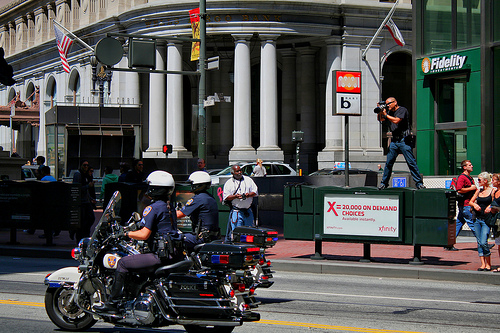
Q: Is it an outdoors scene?
A: Yes, it is outdoors.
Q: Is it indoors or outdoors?
A: It is outdoors.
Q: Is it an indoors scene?
A: No, it is outdoors.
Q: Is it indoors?
A: No, it is outdoors.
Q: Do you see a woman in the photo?
A: Yes, there is a woman.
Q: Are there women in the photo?
A: Yes, there is a woman.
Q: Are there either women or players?
A: Yes, there is a woman.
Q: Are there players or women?
A: Yes, there is a woman.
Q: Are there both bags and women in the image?
A: No, there is a woman but no bags.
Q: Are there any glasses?
A: No, there are no glasses.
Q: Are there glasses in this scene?
A: No, there are no glasses.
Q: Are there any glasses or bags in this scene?
A: No, there are no glasses or bags.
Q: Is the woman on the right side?
A: Yes, the woman is on the right of the image.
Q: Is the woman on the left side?
A: No, the woman is on the right of the image.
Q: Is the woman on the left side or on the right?
A: The woman is on the right of the image.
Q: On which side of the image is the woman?
A: The woman is on the right of the image.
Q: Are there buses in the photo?
A: No, there are no buses.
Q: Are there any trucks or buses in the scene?
A: No, there are no buses or trucks.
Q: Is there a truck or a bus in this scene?
A: No, there are no buses or trucks.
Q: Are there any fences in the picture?
A: No, there are no fences.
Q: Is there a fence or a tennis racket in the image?
A: No, there are no fences or rackets.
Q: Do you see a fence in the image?
A: No, there are no fences.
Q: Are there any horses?
A: No, there are no horses.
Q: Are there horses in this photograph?
A: No, there are no horses.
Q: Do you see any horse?
A: No, there are no horses.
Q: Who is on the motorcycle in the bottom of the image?
A: The officer is on the motorcycle.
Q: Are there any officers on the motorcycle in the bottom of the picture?
A: Yes, there is an officer on the motorbike.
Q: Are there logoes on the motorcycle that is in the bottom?
A: No, there is an officer on the motorbike.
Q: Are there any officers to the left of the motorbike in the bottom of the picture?
A: Yes, there is an officer to the left of the motorcycle.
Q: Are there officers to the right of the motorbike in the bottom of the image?
A: No, the officer is to the left of the motorcycle.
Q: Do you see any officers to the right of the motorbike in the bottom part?
A: No, the officer is to the left of the motorcycle.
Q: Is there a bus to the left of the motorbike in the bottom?
A: No, there is an officer to the left of the motorbike.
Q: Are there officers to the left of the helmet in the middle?
A: Yes, there is an officer to the left of the helmet.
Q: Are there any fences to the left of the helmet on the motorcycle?
A: No, there is an officer to the left of the helmet.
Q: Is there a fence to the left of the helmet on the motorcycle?
A: No, there is an officer to the left of the helmet.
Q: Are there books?
A: No, there are no books.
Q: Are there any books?
A: No, there are no books.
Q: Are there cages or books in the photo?
A: No, there are no books or cages.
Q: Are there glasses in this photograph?
A: No, there are no glasses.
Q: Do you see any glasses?
A: No, there are no glasses.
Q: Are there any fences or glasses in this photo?
A: No, there are no glasses or fences.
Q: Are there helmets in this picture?
A: Yes, there is a helmet.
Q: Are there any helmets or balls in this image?
A: Yes, there is a helmet.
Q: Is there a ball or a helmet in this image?
A: Yes, there is a helmet.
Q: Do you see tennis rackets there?
A: No, there are no tennis rackets.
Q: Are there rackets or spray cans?
A: No, there are no rackets or spray cans.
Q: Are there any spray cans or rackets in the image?
A: No, there are no rackets or spray cans.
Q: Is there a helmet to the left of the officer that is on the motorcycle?
A: Yes, there is a helmet to the left of the officer.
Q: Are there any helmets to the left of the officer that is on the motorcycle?
A: Yes, there is a helmet to the left of the officer.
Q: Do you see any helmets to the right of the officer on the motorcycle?
A: No, the helmet is to the left of the officer.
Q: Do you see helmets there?
A: Yes, there is a helmet.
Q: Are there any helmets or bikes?
A: Yes, there is a helmet.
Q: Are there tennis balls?
A: No, there are no tennis balls.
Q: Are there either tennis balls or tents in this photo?
A: No, there are no tennis balls or tents.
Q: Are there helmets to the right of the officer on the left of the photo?
A: Yes, there is a helmet to the right of the officer.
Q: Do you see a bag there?
A: No, there are no bags.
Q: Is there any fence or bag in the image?
A: No, there are no bags or fences.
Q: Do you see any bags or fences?
A: No, there are no bags or fences.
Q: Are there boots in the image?
A: Yes, there are boots.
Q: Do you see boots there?
A: Yes, there are boots.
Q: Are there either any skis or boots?
A: Yes, there are boots.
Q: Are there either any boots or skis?
A: Yes, there are boots.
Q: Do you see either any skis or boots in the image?
A: Yes, there are boots.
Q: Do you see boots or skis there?
A: Yes, there are boots.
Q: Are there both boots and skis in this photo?
A: No, there are boots but no skis.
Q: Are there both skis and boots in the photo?
A: No, there are boots but no skis.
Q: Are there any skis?
A: No, there are no skis.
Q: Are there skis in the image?
A: No, there are no skis.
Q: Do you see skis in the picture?
A: No, there are no skis.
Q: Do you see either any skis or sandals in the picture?
A: No, there are no skis or sandals.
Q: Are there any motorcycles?
A: Yes, there is a motorcycle.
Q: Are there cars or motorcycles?
A: Yes, there is a motorcycle.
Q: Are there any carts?
A: No, there are no carts.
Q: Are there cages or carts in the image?
A: No, there are no carts or cages.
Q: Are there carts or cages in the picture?
A: No, there are no carts or cages.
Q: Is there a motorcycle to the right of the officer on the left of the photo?
A: Yes, there is a motorcycle to the right of the officer.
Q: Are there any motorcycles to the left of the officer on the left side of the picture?
A: No, the motorcycle is to the right of the officer.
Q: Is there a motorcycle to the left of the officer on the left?
A: No, the motorcycle is to the right of the officer.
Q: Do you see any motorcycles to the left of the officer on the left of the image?
A: No, the motorcycle is to the right of the officer.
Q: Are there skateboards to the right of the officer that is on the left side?
A: No, there is a motorcycle to the right of the officer.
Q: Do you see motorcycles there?
A: Yes, there is a motorcycle.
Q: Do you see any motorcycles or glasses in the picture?
A: Yes, there is a motorcycle.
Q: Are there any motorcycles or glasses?
A: Yes, there is a motorcycle.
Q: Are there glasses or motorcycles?
A: Yes, there is a motorcycle.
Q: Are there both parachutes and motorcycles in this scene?
A: No, there is a motorcycle but no parachutes.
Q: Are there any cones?
A: No, there are no cones.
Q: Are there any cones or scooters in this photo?
A: No, there are no cones or scooters.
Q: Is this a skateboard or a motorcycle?
A: This is a motorcycle.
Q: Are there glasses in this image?
A: No, there are no glasses.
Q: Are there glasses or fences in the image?
A: No, there are no glasses or fences.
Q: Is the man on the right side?
A: Yes, the man is on the right of the image.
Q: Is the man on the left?
A: No, the man is on the right of the image.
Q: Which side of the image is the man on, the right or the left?
A: The man is on the right of the image.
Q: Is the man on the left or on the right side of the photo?
A: The man is on the right of the image.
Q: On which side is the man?
A: The man is on the right of the image.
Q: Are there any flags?
A: Yes, there is a flag.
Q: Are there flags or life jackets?
A: Yes, there is a flag.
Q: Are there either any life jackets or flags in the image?
A: Yes, there is a flag.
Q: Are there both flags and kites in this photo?
A: No, there is a flag but no kites.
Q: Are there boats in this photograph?
A: No, there are no boats.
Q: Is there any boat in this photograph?
A: No, there are no boats.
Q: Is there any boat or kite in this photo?
A: No, there are no boats or kites.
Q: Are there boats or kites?
A: No, there are no boats or kites.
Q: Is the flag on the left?
A: Yes, the flag is on the left of the image.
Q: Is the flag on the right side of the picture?
A: No, the flag is on the left of the image.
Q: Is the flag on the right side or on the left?
A: The flag is on the left of the image.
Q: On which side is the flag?
A: The flag is on the left of the image.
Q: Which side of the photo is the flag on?
A: The flag is on the left of the image.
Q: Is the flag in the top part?
A: Yes, the flag is in the top of the image.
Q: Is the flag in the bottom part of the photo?
A: No, the flag is in the top of the image.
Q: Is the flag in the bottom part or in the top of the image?
A: The flag is in the top of the image.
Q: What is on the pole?
A: The flag is on the pole.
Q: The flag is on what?
A: The flag is on the pole.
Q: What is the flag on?
A: The flag is on the pole.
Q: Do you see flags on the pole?
A: Yes, there is a flag on the pole.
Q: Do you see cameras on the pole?
A: No, there is a flag on the pole.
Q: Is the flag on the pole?
A: Yes, the flag is on the pole.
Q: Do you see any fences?
A: No, there are no fences.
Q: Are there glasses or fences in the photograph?
A: No, there are no fences or glasses.